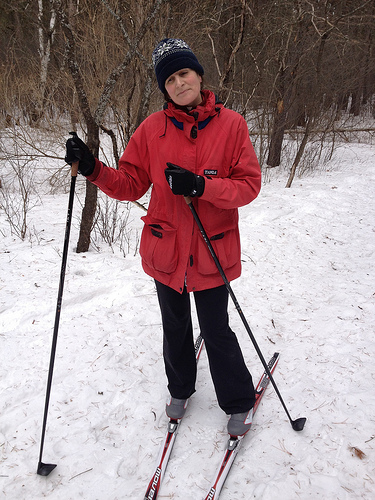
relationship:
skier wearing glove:
[62, 34, 261, 438] [164, 160, 203, 197]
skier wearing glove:
[62, 34, 261, 438] [63, 135, 96, 177]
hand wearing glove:
[164, 161, 193, 197] [162, 160, 205, 200]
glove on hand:
[164, 160, 203, 197] [164, 161, 192, 196]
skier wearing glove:
[62, 34, 261, 438] [163, 156, 217, 203]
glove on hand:
[163, 156, 217, 203] [164, 161, 192, 196]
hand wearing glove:
[164, 161, 192, 196] [62, 130, 205, 196]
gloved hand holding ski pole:
[55, 134, 102, 178] [29, 134, 86, 486]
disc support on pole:
[36, 459, 57, 477] [34, 129, 81, 477]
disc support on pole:
[292, 414, 309, 432] [177, 195, 307, 431]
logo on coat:
[204, 169, 218, 175] [83, 87, 262, 295]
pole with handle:
[36, 176, 76, 476] [69, 160, 79, 176]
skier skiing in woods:
[62, 34, 261, 438] [0, 2, 373, 256]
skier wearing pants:
[62, 34, 261, 438] [151, 276, 258, 418]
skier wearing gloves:
[62, 34, 261, 438] [55, 136, 226, 217]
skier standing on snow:
[62, 34, 261, 438] [248, 211, 291, 312]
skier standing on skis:
[62, 34, 261, 438] [209, 435, 236, 498]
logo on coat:
[202, 168, 220, 173] [100, 108, 264, 290]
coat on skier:
[82, 87, 263, 296] [62, 34, 261, 438]